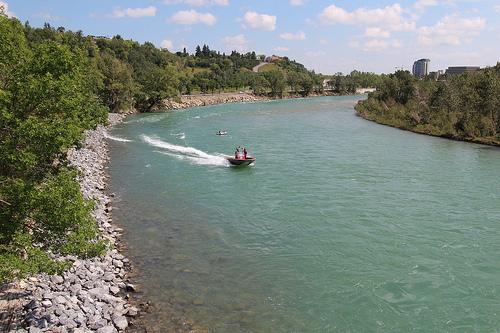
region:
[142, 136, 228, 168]
white waves from boat wake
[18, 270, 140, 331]
large pile of grey rocks on the riverbank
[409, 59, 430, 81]
round shaped skyscraper on the horizon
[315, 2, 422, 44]
group of white fluffy clouds in a blue sky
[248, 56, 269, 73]
small grey roadway on a ridge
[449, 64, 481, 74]
top of a dark brown building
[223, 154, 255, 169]
small speedboat with a red interior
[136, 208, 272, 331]
dark brown wet rocks on bottom of river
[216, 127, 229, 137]
large rock in the middle of river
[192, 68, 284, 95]
group of dark green trees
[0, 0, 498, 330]
This is a river scene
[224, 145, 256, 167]
A boat is on the river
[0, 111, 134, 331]
Rocks are on the river shore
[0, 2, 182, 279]
Trees are along the river bank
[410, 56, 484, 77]
Buildings are in the distance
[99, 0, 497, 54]
Clouds are in the sky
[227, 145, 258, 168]
The boat is red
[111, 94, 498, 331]
This is the river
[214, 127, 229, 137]
A small boat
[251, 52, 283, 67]
A house is on this hill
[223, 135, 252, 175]
boat on green river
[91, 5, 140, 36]
white clouds in blue sky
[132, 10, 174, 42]
white clouds in blue sky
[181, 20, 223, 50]
white clouds in blue sky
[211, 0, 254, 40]
white clouds in blue sky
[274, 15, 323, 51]
white clouds in blue sky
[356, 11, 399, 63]
white clouds in blue sky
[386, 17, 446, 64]
white clouds in blue sky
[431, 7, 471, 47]
white clouds in blue sky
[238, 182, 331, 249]
green river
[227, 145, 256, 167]
A small boat with people on it.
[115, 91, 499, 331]
Large body of green water.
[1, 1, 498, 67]
A blue and white sky.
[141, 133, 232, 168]
Lots of white mini waves coming from the boat in the water.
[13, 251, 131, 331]
Rocky shore on the left close to the camera.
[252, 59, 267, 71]
Curvy road in the distance on the left bank.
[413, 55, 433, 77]
Tall grey skyscraper buildings on the right.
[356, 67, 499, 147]
Land on the right full of trees.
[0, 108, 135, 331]
All of the grey rocky shore on the left.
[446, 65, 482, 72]
Dark grey flat top building to the right.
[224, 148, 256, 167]
speed boat on the water of large river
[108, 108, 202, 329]
river bank inside the water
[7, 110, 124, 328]
river bank outside the water full of rocks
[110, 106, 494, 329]
large river stream with waves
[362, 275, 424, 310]
whirlpool in water up ahead of the boat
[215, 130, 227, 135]
row boat behind speed boad on water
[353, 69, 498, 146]
trees abd bushes on river bank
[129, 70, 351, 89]
trees in background on river bank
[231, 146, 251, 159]
two men standing up in speed boat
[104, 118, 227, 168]
water streaming behind speed boat